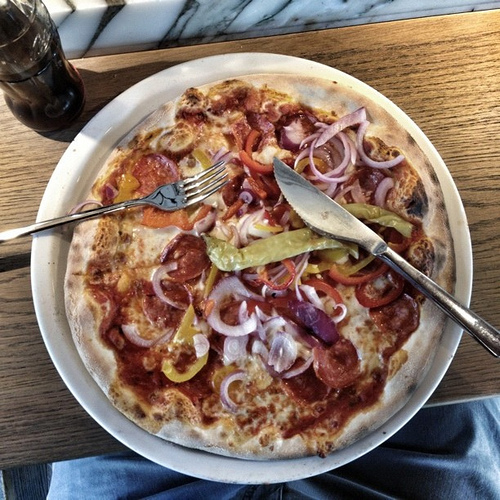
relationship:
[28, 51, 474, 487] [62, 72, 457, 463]
pan holding pizza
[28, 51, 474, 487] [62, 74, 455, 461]
pan of cheese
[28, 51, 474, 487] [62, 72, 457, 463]
pan of pizza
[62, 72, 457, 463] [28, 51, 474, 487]
pizza on pan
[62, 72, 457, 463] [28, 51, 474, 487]
pizza on a pan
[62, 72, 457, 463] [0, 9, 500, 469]
pizza on counter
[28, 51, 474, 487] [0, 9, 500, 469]
pan on a counter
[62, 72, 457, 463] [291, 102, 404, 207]
pizza with onion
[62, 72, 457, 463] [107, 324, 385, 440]
pizza has sauce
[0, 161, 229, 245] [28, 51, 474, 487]
fork on pan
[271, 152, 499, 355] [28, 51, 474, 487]
knife on pan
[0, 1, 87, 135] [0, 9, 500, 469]
bottle on a counter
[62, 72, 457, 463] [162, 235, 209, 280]
pizza has pepperoni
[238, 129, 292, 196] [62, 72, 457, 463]
peppers are on pizza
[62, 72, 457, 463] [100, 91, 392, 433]
pizza has cheese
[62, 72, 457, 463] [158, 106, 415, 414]
pizza has veggies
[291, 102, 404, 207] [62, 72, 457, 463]
onion on pizza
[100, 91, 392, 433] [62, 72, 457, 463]
cheese on pizza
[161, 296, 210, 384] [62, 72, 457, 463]
peppers are on pizza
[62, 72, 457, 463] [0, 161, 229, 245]
pizza with fork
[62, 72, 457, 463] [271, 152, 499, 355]
pizza with knife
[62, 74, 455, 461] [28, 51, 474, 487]
cheese on pan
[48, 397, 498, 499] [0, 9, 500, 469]
cloth are under counter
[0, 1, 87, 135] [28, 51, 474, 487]
bottle near pan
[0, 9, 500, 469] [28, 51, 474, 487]
counter under pan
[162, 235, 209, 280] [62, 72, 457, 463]
pepperoni on pizza